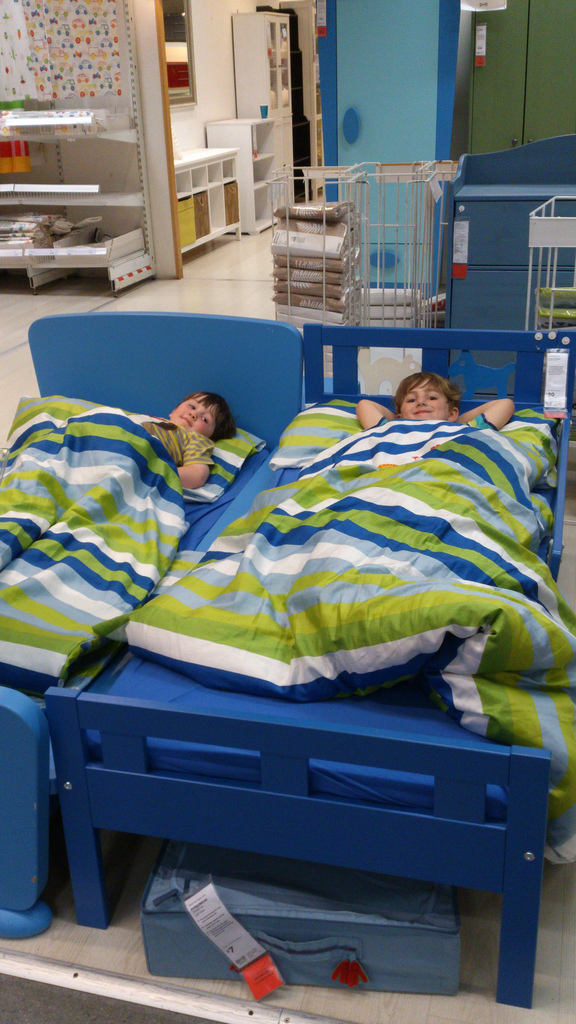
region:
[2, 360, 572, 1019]
A couple of children in bed.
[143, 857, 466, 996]
A gray box under the bed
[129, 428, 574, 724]
A multi color blanket.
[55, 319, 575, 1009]
A dark blue bed.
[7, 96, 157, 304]
A white shelf by a wall.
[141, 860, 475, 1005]
A gray box with red and white tags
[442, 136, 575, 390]
A smoke blue changing table.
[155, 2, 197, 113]
A mirror on a wall.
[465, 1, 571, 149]
A green cabinet with a red and white tag.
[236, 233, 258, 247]
a tile in a floor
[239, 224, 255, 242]
a tile in a floor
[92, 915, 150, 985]
a tile in a floor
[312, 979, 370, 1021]
a tile in a floor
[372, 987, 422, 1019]
a tile in a floor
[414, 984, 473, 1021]
a tile in a floor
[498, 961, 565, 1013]
a tile in a floor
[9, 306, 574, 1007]
Two kids lying on the bed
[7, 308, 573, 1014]
Two blue beds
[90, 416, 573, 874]
Blue, green and white comforter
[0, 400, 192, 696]
Blue, green and white comforter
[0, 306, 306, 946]
Boy lying on blue bed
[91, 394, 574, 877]
Match comforter and pillow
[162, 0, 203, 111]
Mirror on the wall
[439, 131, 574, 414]
Blue changing table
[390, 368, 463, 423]
face of a boy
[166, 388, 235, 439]
Face of a boy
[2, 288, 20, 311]
a tile in a floor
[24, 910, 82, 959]
a tile in a floor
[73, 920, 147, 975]
a tile in a floor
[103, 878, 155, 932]
a tile in a floor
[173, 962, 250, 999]
a tile in a floor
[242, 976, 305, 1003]
a tile in a floor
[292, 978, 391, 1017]
a tile in a floor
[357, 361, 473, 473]
a boy in the bed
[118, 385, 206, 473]
a boy in the bed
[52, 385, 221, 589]
a blanket on the bed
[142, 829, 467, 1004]
large wide blue case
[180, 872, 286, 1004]
long thin plastic tag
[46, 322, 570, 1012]
large wide wooden blue bed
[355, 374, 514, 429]
small kid in bed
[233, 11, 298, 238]
large tall wide wooden white cabinet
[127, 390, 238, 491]
boy laying in bed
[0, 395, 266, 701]
large wide thick blanket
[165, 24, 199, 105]
large square wide mirror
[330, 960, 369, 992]
red case zipper handle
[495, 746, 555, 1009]
tall blue wooden bed leg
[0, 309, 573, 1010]
two blue beds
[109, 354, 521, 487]
two kids in the beds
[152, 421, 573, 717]
bed cover is striped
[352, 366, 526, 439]
boy has his hands behind his head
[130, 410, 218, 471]
boy has a striped shirt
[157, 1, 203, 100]
mirror on the wall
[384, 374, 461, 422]
boy is smiling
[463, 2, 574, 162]
cabinet is green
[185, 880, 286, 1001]
price tag on the package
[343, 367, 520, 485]
a boy laying on a bed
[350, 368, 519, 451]
a boy with his hands behind his head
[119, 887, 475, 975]
a blue suitcase on the floor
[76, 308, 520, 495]
two boys laying on beds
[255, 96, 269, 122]
a blue plastic cup